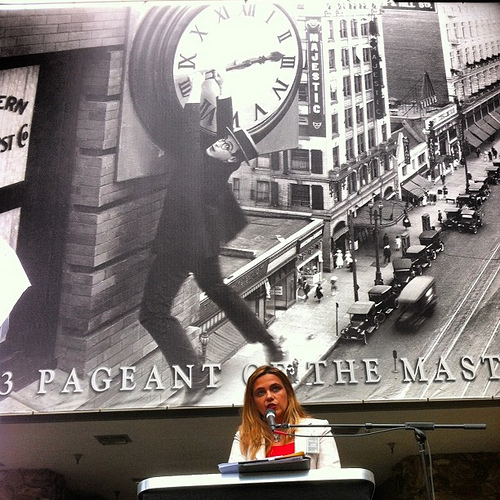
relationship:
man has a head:
[139, 71, 286, 407] [206, 125, 260, 165]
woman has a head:
[228, 366, 342, 469] [245, 365, 303, 420]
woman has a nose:
[228, 366, 342, 469] [265, 388, 274, 400]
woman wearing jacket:
[228, 366, 342, 469] [228, 419, 342, 470]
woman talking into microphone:
[228, 366, 342, 469] [263, 408, 279, 433]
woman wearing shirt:
[228, 366, 342, 469] [267, 442, 297, 457]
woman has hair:
[228, 366, 342, 469] [237, 365, 310, 460]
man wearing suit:
[139, 71, 286, 407] [139, 98, 273, 377]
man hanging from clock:
[139, 71, 286, 407] [127, 1, 304, 156]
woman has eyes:
[228, 366, 342, 469] [254, 385, 281, 395]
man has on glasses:
[139, 71, 286, 407] [218, 134, 235, 158]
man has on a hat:
[139, 71, 286, 407] [225, 123, 260, 168]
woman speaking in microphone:
[228, 366, 342, 469] [263, 408, 279, 433]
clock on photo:
[127, 1, 304, 156] [1, 0, 500, 418]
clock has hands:
[127, 1, 304, 156] [204, 53, 286, 81]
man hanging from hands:
[139, 71, 286, 407] [204, 53, 286, 81]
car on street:
[396, 276, 437, 334] [295, 174, 499, 400]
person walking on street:
[435, 210, 445, 226] [295, 174, 499, 400]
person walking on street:
[315, 284, 324, 305] [295, 174, 499, 400]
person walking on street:
[329, 275, 339, 298] [295, 174, 499, 400]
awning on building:
[462, 108, 500, 148] [384, 3, 500, 152]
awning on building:
[402, 175, 436, 198] [388, 118, 433, 206]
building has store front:
[386, 97, 463, 183] [429, 108, 461, 174]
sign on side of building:
[306, 17, 325, 135] [228, 3, 403, 273]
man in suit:
[139, 71, 286, 407] [139, 98, 273, 377]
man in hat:
[139, 71, 286, 407] [225, 123, 260, 168]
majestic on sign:
[308, 32, 320, 115] [306, 17, 325, 135]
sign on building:
[306, 17, 325, 135] [228, 3, 403, 273]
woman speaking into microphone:
[228, 366, 342, 469] [263, 408, 279, 433]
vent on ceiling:
[92, 432, 132, 445] [0, 408, 499, 499]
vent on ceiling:
[332, 423, 361, 436] [0, 408, 499, 499]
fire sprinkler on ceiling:
[73, 452, 83, 463] [0, 408, 499, 499]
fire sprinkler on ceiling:
[113, 489, 121, 499] [0, 408, 499, 499]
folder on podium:
[237, 457, 312, 471] [135, 469, 377, 499]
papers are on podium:
[217, 462, 239, 475] [135, 469, 377, 499]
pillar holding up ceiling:
[378, 453, 499, 499] [0, 408, 499, 499]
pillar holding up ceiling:
[0, 469, 66, 498] [0, 408, 499, 499]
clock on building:
[127, 1, 304, 156] [3, 3, 195, 408]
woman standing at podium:
[228, 366, 342, 469] [135, 469, 377, 499]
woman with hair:
[228, 366, 342, 469] [237, 365, 310, 460]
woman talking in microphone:
[228, 366, 342, 469] [263, 408, 279, 433]